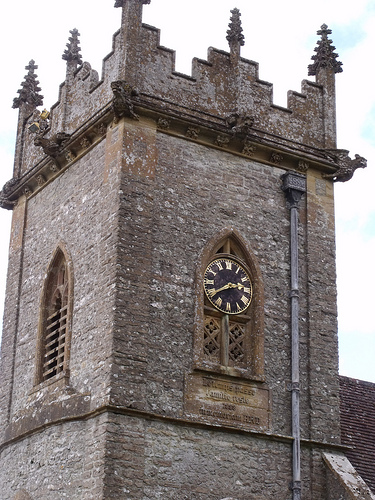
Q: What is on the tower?
A: A clock.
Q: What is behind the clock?
A: A window.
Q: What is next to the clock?
A: A drain pipe.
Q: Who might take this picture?
A: A tourist.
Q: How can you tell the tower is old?
A: There is rust.